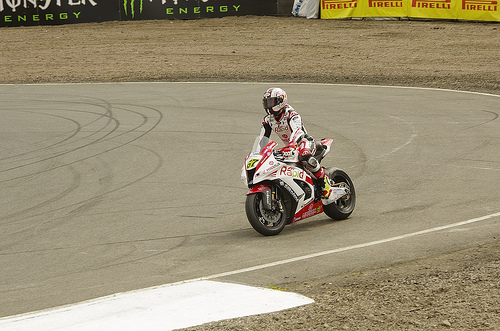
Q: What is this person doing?
A: Riding motorcycle during race.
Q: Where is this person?
A: On the motorcycle.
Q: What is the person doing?
A: Riding motorcycle.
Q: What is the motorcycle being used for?
A: Riding.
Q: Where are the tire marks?
A: On a gray asphalt course.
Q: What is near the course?
A: Patch of dirt.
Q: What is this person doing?
A: Riding on motorcycle.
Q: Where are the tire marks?
A: In the track.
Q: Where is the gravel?
A: Side of track.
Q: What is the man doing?
A: Riding a motorcycle.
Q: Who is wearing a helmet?
A: A man.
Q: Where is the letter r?
A: Bike.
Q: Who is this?
A: Racer.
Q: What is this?
A: MOTOR GP.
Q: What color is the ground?
A: Gray.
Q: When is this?
A: Daytime.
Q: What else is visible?
A: Brake marks.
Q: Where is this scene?
A: Motocross race.